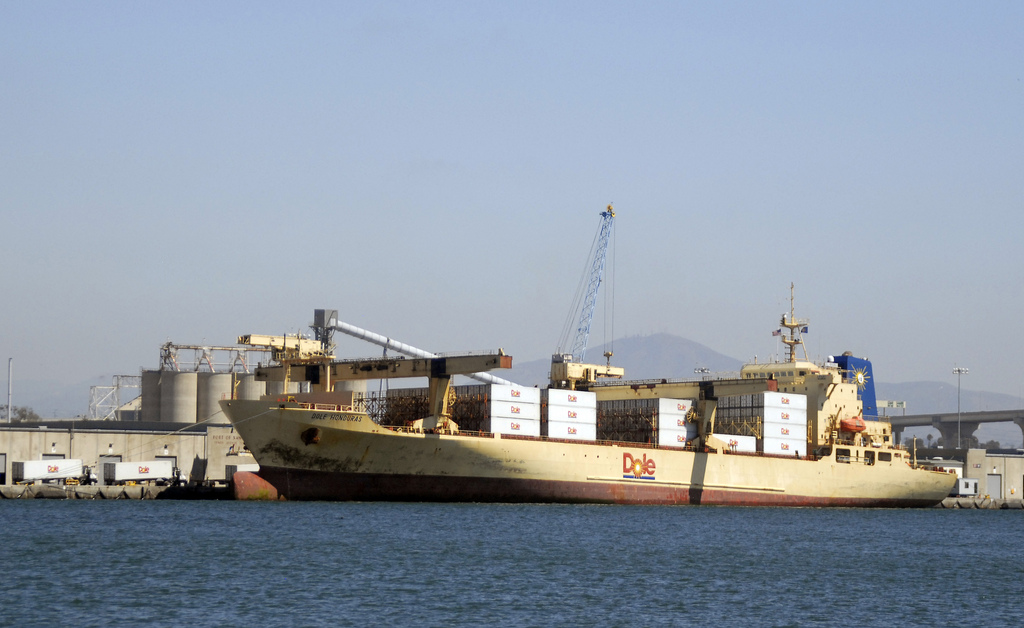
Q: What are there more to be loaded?
A: Trailers.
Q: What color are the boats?
A: Red and white.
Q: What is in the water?
A: A boat.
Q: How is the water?
A: Calm.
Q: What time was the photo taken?
A: Daytime.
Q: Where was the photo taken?
A: Near a large port.